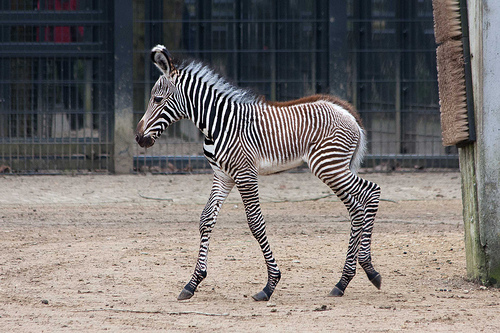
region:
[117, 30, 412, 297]
this is a zebra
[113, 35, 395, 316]
the zebra is walking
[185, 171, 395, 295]
these are the legs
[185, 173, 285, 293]
the legs are long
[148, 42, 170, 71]
these are the ears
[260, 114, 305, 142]
the zebra is small in size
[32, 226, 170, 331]
this is the ground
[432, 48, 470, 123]
this is the brush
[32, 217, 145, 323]
the ground is dry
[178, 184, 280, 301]
The front legs of the zebra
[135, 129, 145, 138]
The nose of the zebra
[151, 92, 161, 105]
The left eye of the zebra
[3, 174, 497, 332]
Dirt beneath the zebra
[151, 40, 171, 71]
The ears of the zebra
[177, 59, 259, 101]
The mane of the zebra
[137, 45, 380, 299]
A zebra in the enclosure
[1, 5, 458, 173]
A fence near the zebra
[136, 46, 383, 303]
The zebra is small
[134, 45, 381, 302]
The zebra has black and white stripes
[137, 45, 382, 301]
black and white small zebra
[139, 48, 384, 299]
zebra inside of pen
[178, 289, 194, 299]
black hoof of zebra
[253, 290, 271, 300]
black hoof of zebra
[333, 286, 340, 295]
black hoof of zebra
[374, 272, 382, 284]
black hoof of zebra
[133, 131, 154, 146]
black nose of zebra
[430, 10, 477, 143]
brush hanging on wall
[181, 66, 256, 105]
white main of baby zebra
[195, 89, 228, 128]
black and white stripes on a zebra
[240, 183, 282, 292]
the leg of a zebra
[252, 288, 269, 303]
the hoof of a zebra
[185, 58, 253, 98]
the mane of a zebra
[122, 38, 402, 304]
a baby zebra walking in the dirt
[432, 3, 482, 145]
a black broom with brown bristles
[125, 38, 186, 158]
the head of a baby zebra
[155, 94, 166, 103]
the eye of a zebra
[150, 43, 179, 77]
the ears of a zebra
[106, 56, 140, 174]
mud on a fence post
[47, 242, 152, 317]
this is the ground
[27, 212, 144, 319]
the ground is sandy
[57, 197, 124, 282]
this is the sand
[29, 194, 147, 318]
the sand is brown in color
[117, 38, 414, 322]
this is a zebra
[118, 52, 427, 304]
the zebra is small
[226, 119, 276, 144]
the fur is black and white in color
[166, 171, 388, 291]
these are the feet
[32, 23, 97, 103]
the area is metallic